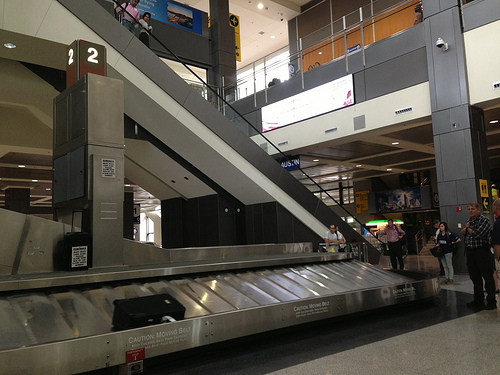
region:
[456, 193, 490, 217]
the head of a man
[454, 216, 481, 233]
the hand of a man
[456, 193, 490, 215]
the eyes of a man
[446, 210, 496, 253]
the arm of a man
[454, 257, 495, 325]
the legs of a man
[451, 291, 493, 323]
the foot of a man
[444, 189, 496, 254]
a man wearing a shirt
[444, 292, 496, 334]
a man wearing shoes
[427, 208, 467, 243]
the head of a woman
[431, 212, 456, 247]
the hair of a woman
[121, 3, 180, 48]
people standing on the stairs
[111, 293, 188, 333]
a black suitcase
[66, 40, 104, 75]
a number on a sign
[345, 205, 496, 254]
people standing waiting for luggage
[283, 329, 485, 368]
the tile on the floor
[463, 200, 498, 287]
a man wearing a checkered shirt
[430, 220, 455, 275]
a woman carrying a bag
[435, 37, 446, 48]
a camera on the wall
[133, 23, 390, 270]
a stair case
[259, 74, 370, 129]
a sign on the wall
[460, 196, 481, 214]
head of a person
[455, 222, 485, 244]
hand of a person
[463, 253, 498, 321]
legs of a person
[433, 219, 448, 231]
head of a person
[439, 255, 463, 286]
legs of a person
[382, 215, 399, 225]
head of a person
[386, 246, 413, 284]
legs of a person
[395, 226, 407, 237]
arm of a person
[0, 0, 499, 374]
Airport luggage pickup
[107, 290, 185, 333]
Large black suitcase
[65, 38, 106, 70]
Lit up number two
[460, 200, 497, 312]
Man wearing a plaid shirt and black pants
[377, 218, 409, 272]
Man wearing a pink dress shirt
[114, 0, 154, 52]
Two people riding down an escalator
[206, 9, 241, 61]
Yellow airport sign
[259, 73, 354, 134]
White rectangular sign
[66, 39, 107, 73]
white on black number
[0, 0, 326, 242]
white wall of the escalator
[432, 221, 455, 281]
woman standing by the escalators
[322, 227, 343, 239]
white shirt man is wearing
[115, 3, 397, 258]
black railing on the side of the escalator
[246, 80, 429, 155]
white paneling above the floor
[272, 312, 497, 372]
white tile on the floor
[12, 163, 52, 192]
lights in the ceiling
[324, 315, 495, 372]
floor is shiny tile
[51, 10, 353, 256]
escalator in far distance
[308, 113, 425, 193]
white and recessed lights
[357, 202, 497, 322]
people walking in mall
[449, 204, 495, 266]
man has plaid shirt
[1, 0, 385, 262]
the escalator is very tall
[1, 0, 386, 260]
the people on the escalator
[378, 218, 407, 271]
the man is standing up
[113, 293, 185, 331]
the luggage is black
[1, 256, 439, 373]
the luggage on the conveyor belt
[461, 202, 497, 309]
the man is standing up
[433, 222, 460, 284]
the woman is standing up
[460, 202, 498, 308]
the man is wearing pants